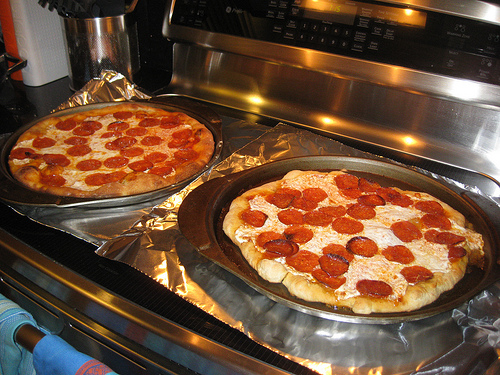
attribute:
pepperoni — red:
[331, 212, 361, 234]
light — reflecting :
[391, 127, 428, 152]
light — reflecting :
[393, 2, 421, 22]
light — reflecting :
[307, 107, 347, 132]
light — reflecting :
[240, 83, 269, 113]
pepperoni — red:
[288, 247, 320, 277]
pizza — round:
[222, 136, 489, 323]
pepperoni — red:
[316, 251, 347, 274]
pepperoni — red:
[324, 200, 378, 232]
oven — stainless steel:
[14, 225, 217, 372]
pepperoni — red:
[399, 263, 442, 286]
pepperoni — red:
[269, 190, 296, 206]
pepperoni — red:
[357, 279, 393, 298]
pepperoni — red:
[352, 271, 393, 306]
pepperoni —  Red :
[277, 208, 307, 230]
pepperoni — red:
[273, 181, 335, 271]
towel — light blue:
[1, 295, 38, 373]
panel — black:
[173, 0, 498, 85]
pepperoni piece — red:
[270, 194, 355, 241]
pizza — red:
[165, 120, 430, 332]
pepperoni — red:
[263, 182, 301, 209]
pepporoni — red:
[258, 228, 303, 259]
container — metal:
[56, 7, 139, 93]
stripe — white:
[1, 299, 24, 317]